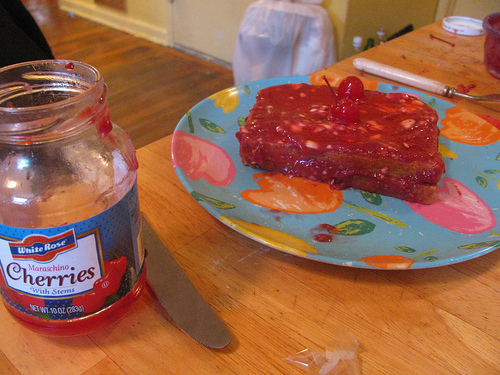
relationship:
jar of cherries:
[14, 44, 140, 333] [324, 70, 373, 121]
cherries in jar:
[324, 70, 373, 121] [14, 44, 140, 333]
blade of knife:
[124, 219, 240, 348] [59, 146, 235, 361]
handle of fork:
[355, 55, 444, 90] [353, 51, 497, 117]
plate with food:
[170, 64, 492, 278] [249, 70, 463, 219]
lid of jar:
[443, 9, 489, 49] [14, 44, 140, 333]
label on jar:
[3, 189, 145, 309] [14, 44, 140, 333]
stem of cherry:
[319, 75, 337, 99] [341, 72, 361, 96]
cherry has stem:
[341, 72, 361, 96] [319, 75, 337, 99]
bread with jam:
[259, 89, 424, 167] [273, 144, 388, 201]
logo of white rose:
[8, 231, 89, 262] [14, 237, 69, 255]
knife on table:
[59, 146, 235, 361] [43, 30, 473, 334]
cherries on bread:
[324, 70, 373, 121] [259, 89, 424, 167]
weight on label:
[24, 297, 85, 323] [3, 189, 145, 309]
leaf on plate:
[331, 218, 380, 246] [170, 64, 492, 278]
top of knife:
[169, 281, 243, 359] [59, 146, 235, 361]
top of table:
[183, 239, 458, 339] [43, 30, 473, 334]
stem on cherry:
[319, 75, 337, 99] [341, 72, 361, 96]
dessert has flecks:
[259, 89, 424, 167] [299, 134, 322, 158]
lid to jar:
[443, 9, 489, 49] [14, 44, 140, 333]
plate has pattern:
[170, 64, 492, 278] [255, 174, 420, 239]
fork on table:
[353, 51, 497, 117] [43, 30, 473, 334]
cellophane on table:
[277, 330, 366, 373] [43, 30, 473, 334]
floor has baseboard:
[29, 27, 216, 143] [61, 0, 173, 33]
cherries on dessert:
[324, 70, 373, 121] [259, 89, 424, 167]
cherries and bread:
[324, 70, 373, 121] [259, 89, 424, 167]